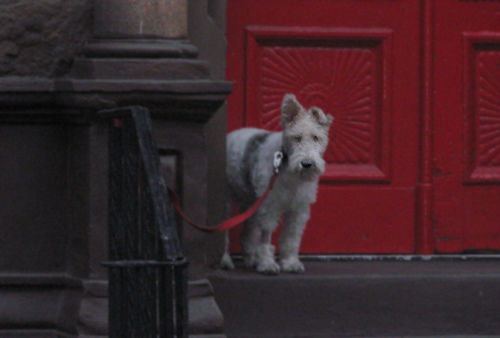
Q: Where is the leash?
A: Around the dog's neck.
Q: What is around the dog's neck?
A: A leash.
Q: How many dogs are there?
A: One.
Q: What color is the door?
A: Red.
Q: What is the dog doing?
A: Standing still.